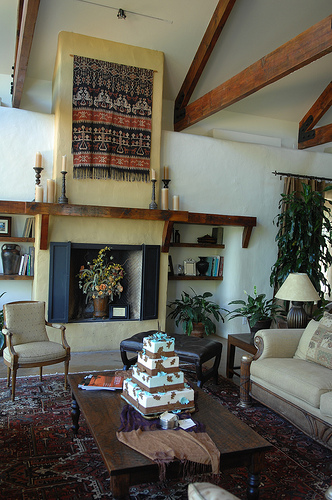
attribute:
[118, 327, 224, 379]
bench — black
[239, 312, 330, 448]
sofa — wood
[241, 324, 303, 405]
rolled arm — tan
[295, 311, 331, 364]
pillow — tan, square 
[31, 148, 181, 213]
candlestick — black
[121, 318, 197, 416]
cake — blue, white, brown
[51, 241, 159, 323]
door — black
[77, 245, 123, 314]
arrangement — floral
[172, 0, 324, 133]
beam — wood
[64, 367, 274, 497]
coffee table — wooden, stained , wood, brown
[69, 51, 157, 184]
fabric — fringed, art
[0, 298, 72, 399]
chair — empty, upholstered, wooden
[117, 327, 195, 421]
cake — BIG, TALL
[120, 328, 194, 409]
cake — BIG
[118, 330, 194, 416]
cake — BIG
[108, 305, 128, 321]
paper — FRAMED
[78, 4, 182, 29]
light — SINGLE, CEILING MOUNTED, TRACK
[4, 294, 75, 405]
chair — WOOD FRAMED, QUEEN ANNE STYLE, ARMED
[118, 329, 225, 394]
ottoman — black, leather like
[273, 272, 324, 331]
lamp — dark, table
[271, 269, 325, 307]
shade — tan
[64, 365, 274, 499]
table — wooden, coffee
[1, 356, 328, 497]
rug — area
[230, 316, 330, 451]
couch — upholstered, tan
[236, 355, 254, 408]
leg — bronze like, marble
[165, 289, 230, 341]
plant — house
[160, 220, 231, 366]
nook — book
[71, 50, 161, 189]
hanging — decorative, wall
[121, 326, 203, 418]
cake — brown, white, blue, decorative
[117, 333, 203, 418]
cake — colorful, four tiered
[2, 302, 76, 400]
chair — two toned, brown, upholstered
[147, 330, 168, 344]
trimmings — light blue